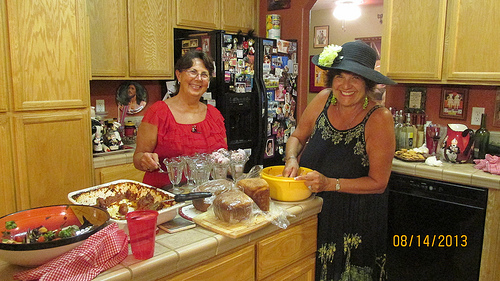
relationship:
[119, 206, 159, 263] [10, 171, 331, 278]
cup on counter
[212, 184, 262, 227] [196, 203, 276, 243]
bread on cutting board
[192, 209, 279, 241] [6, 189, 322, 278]
cutting board on counter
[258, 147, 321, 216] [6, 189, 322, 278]
bowl on counter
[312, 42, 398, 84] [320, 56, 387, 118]
hat on head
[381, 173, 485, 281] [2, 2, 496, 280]
dishwasher in kitchen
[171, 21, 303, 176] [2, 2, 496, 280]
refrigerator in kitchen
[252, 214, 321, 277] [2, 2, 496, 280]
drawer in kitchen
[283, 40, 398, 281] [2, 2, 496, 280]
lady standing in kitchen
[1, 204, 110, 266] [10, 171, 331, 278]
bowl on counter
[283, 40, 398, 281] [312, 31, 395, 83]
lady wearing hat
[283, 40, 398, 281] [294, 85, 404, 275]
lady wearing dress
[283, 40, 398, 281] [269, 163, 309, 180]
lady mixing food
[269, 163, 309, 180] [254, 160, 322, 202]
food in bowl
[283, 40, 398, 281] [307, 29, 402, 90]
lady wearing hat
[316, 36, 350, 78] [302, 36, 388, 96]
flower on hat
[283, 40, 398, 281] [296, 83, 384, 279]
lady wearing dress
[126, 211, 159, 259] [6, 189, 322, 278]
cup on counter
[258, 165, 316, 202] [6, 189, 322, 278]
bowl on counter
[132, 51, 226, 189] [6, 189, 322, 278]
lady standing behind counter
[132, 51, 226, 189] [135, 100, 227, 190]
lady wearing shirt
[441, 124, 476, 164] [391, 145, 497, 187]
pitcher on counter top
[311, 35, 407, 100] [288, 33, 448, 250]
hat on lady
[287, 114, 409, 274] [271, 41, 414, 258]
dress on lady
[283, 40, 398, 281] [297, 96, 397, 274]
lady wearing dress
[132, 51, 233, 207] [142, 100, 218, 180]
lady wearing top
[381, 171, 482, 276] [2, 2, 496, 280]
dishwasher in kitchen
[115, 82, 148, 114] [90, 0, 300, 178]
jesus painting on wall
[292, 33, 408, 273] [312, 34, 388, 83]
lady wearing hat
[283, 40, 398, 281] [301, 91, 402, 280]
lady wearing dress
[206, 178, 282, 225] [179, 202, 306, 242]
bread loaves on cutting board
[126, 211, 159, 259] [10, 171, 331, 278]
cup on counter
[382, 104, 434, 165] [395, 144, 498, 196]
liquor bottles on counter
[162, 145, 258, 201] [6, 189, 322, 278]
dessert cups on counter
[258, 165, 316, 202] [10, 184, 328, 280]
bowl on counter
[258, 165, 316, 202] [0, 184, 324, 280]
bowl on counter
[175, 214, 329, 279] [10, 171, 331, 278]
drawers on counter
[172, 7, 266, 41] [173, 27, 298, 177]
cabinets above fridge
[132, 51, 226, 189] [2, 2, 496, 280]
lady standing in a kitchen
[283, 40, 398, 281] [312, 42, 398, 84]
lady wearing a hat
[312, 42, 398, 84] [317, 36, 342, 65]
hat with flower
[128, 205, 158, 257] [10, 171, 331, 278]
glass on counter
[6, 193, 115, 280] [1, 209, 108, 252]
bowl containing salad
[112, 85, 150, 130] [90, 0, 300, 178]
jesus painting on wall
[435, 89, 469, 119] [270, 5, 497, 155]
painting on a wall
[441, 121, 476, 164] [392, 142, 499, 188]
pitcher on counter